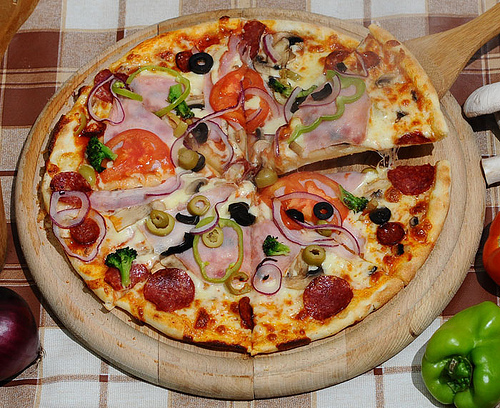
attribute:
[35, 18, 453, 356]
pizza crust — burned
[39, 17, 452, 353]
pizza — large, slice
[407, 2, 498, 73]
spatula — wooden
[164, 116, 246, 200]
olive — black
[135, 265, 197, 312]
pepperoni — slice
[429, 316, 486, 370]
pepper — green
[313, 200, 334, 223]
olive slice — black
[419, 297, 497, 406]
bell pepper — green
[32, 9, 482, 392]
dish — wooden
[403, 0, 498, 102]
spatula — wooden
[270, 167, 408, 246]
pepper — green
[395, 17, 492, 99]
handle — brown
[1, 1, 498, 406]
tablecloth — brown, plaid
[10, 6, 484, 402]
board — wooden